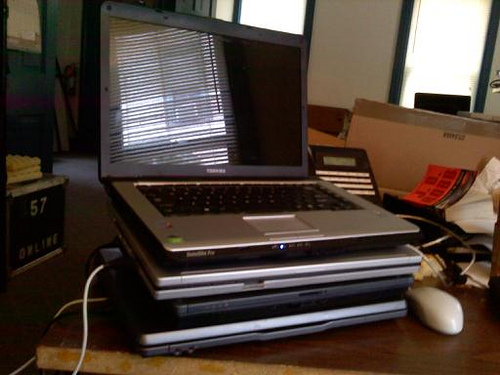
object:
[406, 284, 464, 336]
mouse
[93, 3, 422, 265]
laptop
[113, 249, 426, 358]
laptop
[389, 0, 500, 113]
window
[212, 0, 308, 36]
window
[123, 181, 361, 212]
keyboard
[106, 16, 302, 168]
screen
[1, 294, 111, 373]
cable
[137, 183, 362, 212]
key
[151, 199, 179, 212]
key